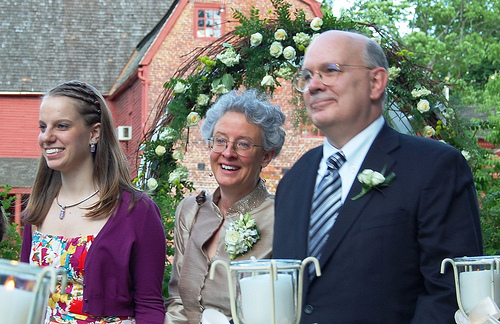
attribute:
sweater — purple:
[14, 180, 163, 322]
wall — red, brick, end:
[81, 46, 261, 156]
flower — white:
[269, 40, 281, 57]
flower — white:
[415, 97, 428, 112]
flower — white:
[283, 45, 297, 61]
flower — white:
[309, 17, 324, 30]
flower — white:
[186, 110, 202, 125]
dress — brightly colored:
[28, 223, 95, 322]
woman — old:
[207, 113, 287, 230]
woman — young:
[6, 83, 171, 322]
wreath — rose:
[145, 12, 435, 123]